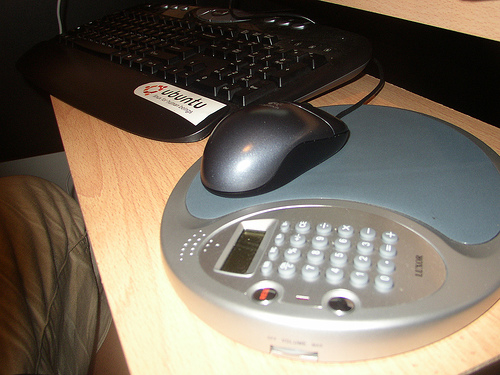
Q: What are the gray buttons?
A: A keypad.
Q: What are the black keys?
A: A keyboard.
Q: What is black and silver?
A: The mouse.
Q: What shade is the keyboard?
A: Black.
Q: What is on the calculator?
A: Buttons.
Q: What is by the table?
A: A leg.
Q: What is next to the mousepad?
A: A calculator.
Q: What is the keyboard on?
A: A mousepad.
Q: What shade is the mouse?
A: Black and silver.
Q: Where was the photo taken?
A: At a desk.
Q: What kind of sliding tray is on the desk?
A: A keyboard tray.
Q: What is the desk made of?
A: Wood.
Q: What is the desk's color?
A: Light brown.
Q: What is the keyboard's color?
A: Black.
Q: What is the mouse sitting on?
A: A mousepad.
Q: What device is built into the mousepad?
A: A calculator.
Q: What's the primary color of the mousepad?
A: Gray.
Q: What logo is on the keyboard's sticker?
A: Ubuntu.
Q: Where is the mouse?
A: On the mouse pad.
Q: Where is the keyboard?
A: Beside the mousepad.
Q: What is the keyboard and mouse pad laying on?
A: Desk.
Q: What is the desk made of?
A: Wood.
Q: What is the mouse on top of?
A: Mouse pad.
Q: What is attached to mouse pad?
A: Calculator.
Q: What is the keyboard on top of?
A: Desk.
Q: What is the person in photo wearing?
A: Khaki shorts.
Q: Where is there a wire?
A: Behind mouse.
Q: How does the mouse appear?
A: Shiny.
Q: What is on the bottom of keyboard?
A: Brand name.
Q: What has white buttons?
A: Calculator.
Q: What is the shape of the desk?
A: Rectangular.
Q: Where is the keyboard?
A: Next to the mouse.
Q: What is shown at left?
A: A leg.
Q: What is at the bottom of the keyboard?
A: A sticker.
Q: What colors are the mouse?
A: Grey and black.